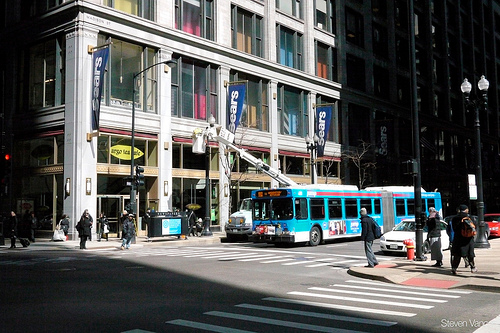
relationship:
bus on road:
[246, 184, 448, 246] [2, 231, 496, 331]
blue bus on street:
[251, 181, 442, 248] [26, 244, 429, 330]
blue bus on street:
[251, 181, 442, 248] [0, 229, 404, 331]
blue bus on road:
[251, 181, 447, 250] [30, 242, 367, 321]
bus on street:
[246, 184, 448, 246] [4, 234, 496, 331]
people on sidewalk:
[422, 202, 480, 278] [355, 252, 497, 289]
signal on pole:
[84, 120, 106, 157] [412, 128, 425, 159]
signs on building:
[36, 55, 393, 185] [48, 13, 423, 253]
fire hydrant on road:
[402, 233, 414, 258] [0, 238, 500, 332]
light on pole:
[472, 70, 497, 95] [462, 95, 498, 252]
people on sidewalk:
[352, 203, 477, 276] [370, 197, 495, 267]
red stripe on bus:
[317, 192, 408, 195] [246, 184, 448, 246]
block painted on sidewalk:
[393, 273, 472, 300] [348, 228, 499, 287]